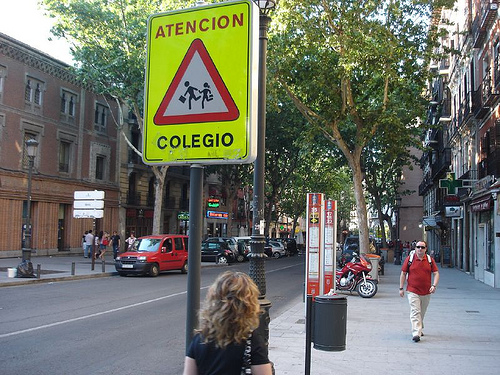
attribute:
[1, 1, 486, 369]
scene — daytime, downtown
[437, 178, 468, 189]
sign — green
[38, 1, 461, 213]
trees — green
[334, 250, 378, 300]
bike — red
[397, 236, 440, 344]
person — walking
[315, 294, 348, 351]
trashcan — gray, black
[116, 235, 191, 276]
car — red, parked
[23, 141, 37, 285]
light — here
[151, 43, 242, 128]
triangle — red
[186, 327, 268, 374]
shirt — black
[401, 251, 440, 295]
shirt — red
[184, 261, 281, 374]
woman — walking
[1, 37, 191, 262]
building — apartments